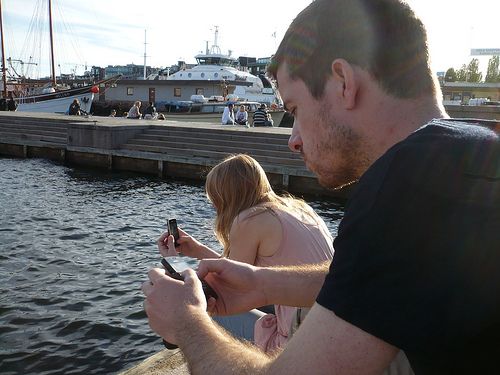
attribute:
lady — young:
[170, 145, 392, 351]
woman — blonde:
[141, 126, 323, 310]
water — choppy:
[8, 148, 324, 360]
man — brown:
[255, 17, 450, 172]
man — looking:
[144, 0, 495, 370]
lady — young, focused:
[166, 152, 346, 373]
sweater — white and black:
[312, 115, 498, 373]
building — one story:
[92, 81, 242, 107]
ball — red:
[91, 83, 102, 93]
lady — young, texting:
[195, 149, 315, 270]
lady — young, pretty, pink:
[198, 153, 345, 352]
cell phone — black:
[161, 251, 221, 302]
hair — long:
[204, 152, 323, 243]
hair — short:
[271, 2, 444, 98]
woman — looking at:
[189, 137, 337, 322]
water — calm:
[0, 146, 345, 374]